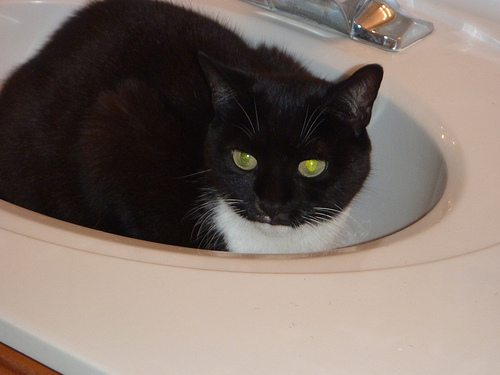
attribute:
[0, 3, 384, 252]
cat — white, black, sitting, medium sized, mostly black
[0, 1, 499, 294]
sink — white, porcelain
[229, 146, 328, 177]
eyes — bright green, green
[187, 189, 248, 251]
whiskers — short, white, thick, long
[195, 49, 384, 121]
ears — small, pointy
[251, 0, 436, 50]
faucet — chrome, silver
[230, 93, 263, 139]
whiskers — long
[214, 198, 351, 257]
patch — white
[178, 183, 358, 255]
chest — white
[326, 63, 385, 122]
ear — black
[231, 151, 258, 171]
left eye — green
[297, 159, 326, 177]
right eye — green